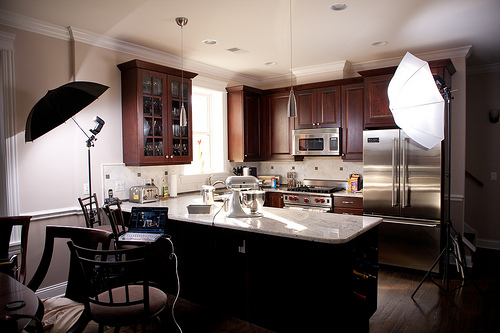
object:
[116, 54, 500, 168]
cabinet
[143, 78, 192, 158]
glass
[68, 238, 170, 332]
chair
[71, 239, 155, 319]
back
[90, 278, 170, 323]
seat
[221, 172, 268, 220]
mixer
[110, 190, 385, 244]
counter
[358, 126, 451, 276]
fridge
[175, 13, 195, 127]
light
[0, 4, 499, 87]
ceiling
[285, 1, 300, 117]
light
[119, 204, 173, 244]
laptop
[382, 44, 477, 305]
umbrellag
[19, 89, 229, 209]
light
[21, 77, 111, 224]
umbrella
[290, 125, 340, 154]
microwave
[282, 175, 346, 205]
stove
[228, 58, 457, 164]
wood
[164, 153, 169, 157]
knob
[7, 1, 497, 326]
kitchen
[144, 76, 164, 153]
window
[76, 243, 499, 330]
floor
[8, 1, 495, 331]
shoot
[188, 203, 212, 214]
pan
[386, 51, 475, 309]
lighting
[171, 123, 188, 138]
glasswear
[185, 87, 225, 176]
view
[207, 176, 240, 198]
sink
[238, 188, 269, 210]
bowl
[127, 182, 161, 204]
toaster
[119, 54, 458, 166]
cabinetry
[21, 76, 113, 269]
source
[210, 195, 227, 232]
cord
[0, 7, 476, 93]
molding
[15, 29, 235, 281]
wall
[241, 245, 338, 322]
cabinet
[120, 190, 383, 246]
countertops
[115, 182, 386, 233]
countertop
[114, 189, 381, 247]
granite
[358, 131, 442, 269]
refrigerator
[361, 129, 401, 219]
doors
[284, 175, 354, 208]
range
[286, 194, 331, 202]
dials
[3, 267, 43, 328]
table